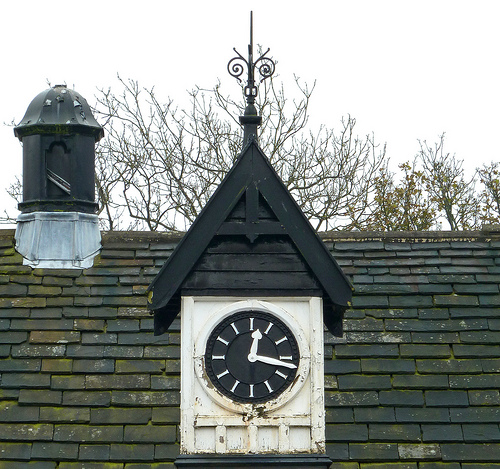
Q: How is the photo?
A: Clear.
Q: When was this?
A: Daytime.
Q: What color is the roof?
A: Grey.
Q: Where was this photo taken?
A: On the street.